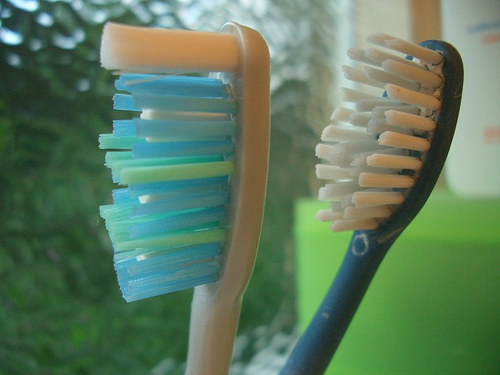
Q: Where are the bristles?
A: On the toothbrushes.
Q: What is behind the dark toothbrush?
A: A cup.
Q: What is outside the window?
A: Trees.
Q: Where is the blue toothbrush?
A: In front of the cup.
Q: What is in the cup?
A: Water.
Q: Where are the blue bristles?
A: On the white toothbrush.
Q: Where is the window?
A: On the wall.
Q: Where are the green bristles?
A: On the white toothbrush.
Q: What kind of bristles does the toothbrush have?
A: Blue and green ones.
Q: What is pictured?
A: Blue and white toothbrushes.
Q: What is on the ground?
A: Green grass.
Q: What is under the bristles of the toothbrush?
A: A plastic handle.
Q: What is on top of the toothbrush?
A: A white bristle.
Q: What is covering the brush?
A: Bristles.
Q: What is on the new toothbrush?
A: Bristles.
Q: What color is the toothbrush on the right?
A: Blue.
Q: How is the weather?
A: Cloudy.